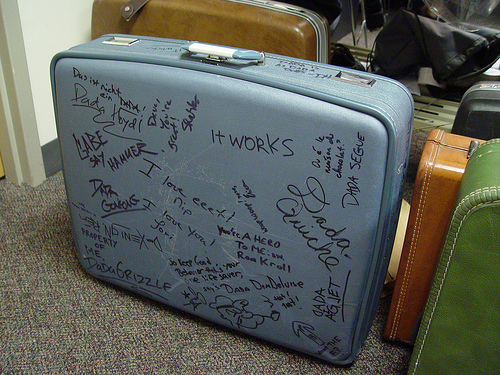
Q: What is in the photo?
A: Suitcases.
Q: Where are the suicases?
A: On the ground.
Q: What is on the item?
A: Writing.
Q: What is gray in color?
A: The ground.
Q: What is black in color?
A: The bag.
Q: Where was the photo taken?
A: In a room.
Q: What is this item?
A: A bag.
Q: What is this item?
A: A briefcase.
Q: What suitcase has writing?
A: A gray colored suitcase.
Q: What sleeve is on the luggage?
A: A black jacket.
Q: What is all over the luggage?
A: Writing.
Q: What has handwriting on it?
A: Suitcase.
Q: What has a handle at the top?
A: Suitcase.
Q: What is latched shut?
A: Suitcase.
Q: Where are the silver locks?
A: Top of suitcase.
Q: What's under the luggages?
A: Carpet.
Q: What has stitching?
A: Brown suitcase.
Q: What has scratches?
A: Suitcase.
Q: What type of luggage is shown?
A: Suitcases.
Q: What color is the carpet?
A: Grey.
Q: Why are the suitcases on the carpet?
A: They are being checked.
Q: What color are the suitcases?
A: Blue, brown, green and black.